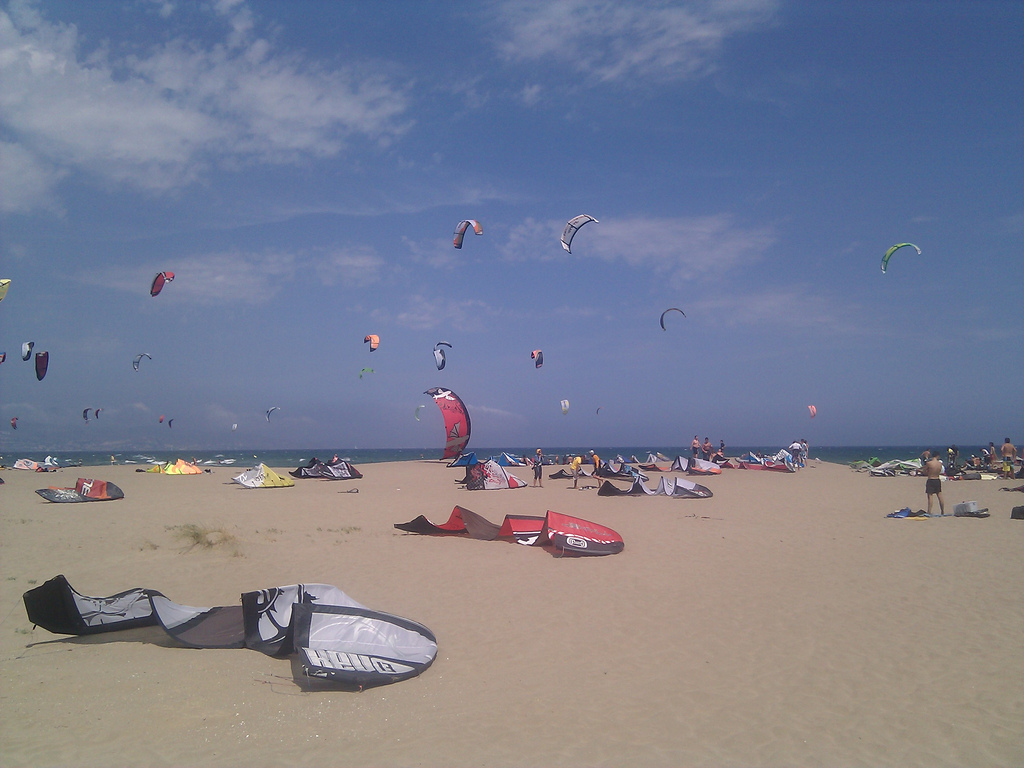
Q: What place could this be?
A: It is a beach.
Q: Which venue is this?
A: This is a beach.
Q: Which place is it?
A: It is a beach.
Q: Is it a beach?
A: Yes, it is a beach.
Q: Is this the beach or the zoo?
A: It is the beach.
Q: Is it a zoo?
A: No, it is a beach.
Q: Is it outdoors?
A: Yes, it is outdoors.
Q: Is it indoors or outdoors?
A: It is outdoors.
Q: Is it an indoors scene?
A: No, it is outdoors.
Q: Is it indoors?
A: No, it is outdoors.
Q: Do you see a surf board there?
A: No, there are no surfboards.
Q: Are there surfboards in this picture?
A: No, there are no surfboards.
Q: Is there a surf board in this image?
A: No, there are no surfboards.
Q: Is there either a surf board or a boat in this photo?
A: No, there are no surfboards or boats.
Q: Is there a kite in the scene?
A: Yes, there is a kite.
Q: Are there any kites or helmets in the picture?
A: Yes, there is a kite.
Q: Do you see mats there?
A: No, there are no mats.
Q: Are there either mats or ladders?
A: No, there are no mats or ladders.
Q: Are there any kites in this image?
A: Yes, there is a kite.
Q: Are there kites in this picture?
A: Yes, there is a kite.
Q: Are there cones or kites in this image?
A: Yes, there is a kite.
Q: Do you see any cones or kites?
A: Yes, there is a kite.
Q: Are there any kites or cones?
A: Yes, there is a kite.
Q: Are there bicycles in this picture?
A: No, there are no bicycles.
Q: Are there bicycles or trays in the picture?
A: No, there are no bicycles or trays.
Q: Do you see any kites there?
A: Yes, there is a kite.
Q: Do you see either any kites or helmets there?
A: Yes, there is a kite.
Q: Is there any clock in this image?
A: No, there are no clocks.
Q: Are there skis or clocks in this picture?
A: No, there are no clocks or skis.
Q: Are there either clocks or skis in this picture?
A: No, there are no clocks or skis.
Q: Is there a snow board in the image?
A: No, there are no snowboards.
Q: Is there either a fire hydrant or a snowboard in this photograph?
A: No, there are no snowboards or fire hydrants.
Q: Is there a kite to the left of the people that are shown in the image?
A: Yes, there are kites to the left of the people.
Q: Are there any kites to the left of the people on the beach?
A: Yes, there are kites to the left of the people.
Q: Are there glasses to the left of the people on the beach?
A: No, there are kites to the left of the people.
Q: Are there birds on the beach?
A: No, there are kites on the beach.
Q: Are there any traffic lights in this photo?
A: No, there are no traffic lights.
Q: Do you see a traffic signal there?
A: No, there are no traffic lights.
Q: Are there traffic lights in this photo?
A: No, there are no traffic lights.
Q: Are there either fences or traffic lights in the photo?
A: No, there are no traffic lights or fences.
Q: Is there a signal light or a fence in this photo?
A: No, there are no traffic lights or fences.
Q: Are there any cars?
A: No, there are no cars.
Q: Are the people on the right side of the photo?
A: Yes, the people are on the right of the image.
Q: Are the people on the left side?
A: No, the people are on the right of the image.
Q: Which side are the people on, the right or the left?
A: The people are on the right of the image.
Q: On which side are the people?
A: The people are on the right of the image.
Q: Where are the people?
A: The people are on the beach.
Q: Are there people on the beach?
A: Yes, there are people on the beach.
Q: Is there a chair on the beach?
A: No, there are people on the beach.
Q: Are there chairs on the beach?
A: No, there are people on the beach.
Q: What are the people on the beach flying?
A: The people are flying the kites.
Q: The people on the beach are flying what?
A: The people are flying the kites.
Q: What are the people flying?
A: The people are flying the kites.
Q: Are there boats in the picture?
A: No, there are no boats.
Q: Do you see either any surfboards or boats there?
A: No, there are no boats or surfboards.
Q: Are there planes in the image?
A: No, there are no planes.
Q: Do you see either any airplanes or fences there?
A: No, there are no airplanes or fences.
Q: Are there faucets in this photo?
A: No, there are no faucets.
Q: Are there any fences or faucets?
A: No, there are no faucets or fences.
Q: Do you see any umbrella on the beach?
A: No, there are kites on the beach.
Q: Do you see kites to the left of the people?
A: Yes, there are kites to the left of the people.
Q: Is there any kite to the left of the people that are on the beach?
A: Yes, there are kites to the left of the people.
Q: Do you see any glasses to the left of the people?
A: No, there are kites to the left of the people.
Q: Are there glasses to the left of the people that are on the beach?
A: No, there are kites to the left of the people.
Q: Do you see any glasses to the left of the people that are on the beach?
A: No, there are kites to the left of the people.